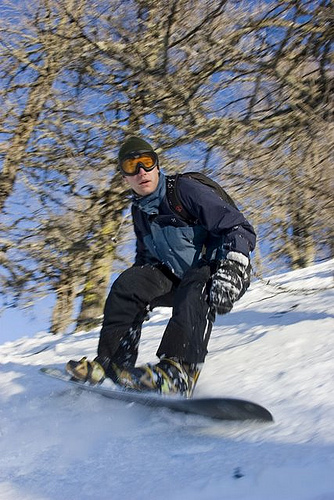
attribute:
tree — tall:
[145, 28, 296, 144]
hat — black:
[113, 134, 158, 160]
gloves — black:
[197, 249, 250, 313]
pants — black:
[79, 263, 225, 367]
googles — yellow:
[117, 148, 158, 175]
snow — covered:
[252, 346, 330, 387]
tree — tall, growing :
[214, 1, 333, 270]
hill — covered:
[1, 255, 333, 497]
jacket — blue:
[132, 180, 259, 275]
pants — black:
[77, 256, 231, 370]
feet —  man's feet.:
[42, 350, 222, 400]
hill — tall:
[12, 226, 321, 496]